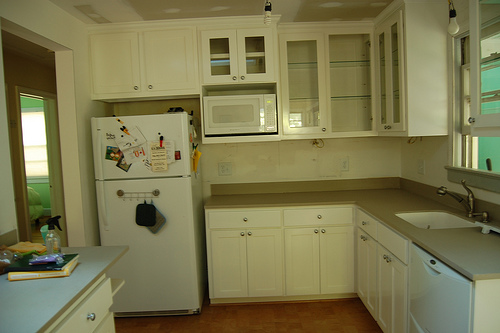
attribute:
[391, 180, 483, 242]
sink — white, grey, metal, silver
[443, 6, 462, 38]
light — white, hanging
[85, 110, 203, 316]
fridge — tall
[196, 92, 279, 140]
microwave — white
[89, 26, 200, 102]
cabinets — white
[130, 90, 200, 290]
fridge — small, white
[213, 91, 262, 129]
microwave — small, white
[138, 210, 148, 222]
pot holder — black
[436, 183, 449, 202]
faucet — metal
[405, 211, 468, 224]
sink — small, white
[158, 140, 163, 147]
magnet — red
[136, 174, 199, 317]
refrigerator — white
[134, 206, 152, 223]
hot pad — hanging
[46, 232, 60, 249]
bottle — clear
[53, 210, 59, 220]
nozzel — black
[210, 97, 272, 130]
microwave — white